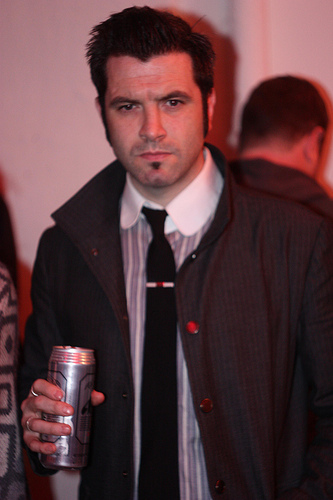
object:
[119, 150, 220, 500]
shirt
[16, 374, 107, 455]
hand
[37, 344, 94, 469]
drink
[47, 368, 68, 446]
wiring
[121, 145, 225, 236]
white collar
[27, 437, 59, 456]
fingers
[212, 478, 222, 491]
button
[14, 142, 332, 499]
jacket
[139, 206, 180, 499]
tie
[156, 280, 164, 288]
detail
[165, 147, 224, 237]
colar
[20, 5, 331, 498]
guy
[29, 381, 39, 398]
ring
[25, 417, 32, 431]
ring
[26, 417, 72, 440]
finger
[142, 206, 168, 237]
knot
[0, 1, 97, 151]
wall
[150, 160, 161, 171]
hair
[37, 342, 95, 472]
can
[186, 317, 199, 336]
button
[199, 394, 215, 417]
button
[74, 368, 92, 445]
writing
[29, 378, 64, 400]
finger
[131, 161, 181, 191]
chin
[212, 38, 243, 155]
shadow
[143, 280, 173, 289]
tack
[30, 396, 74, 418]
finger